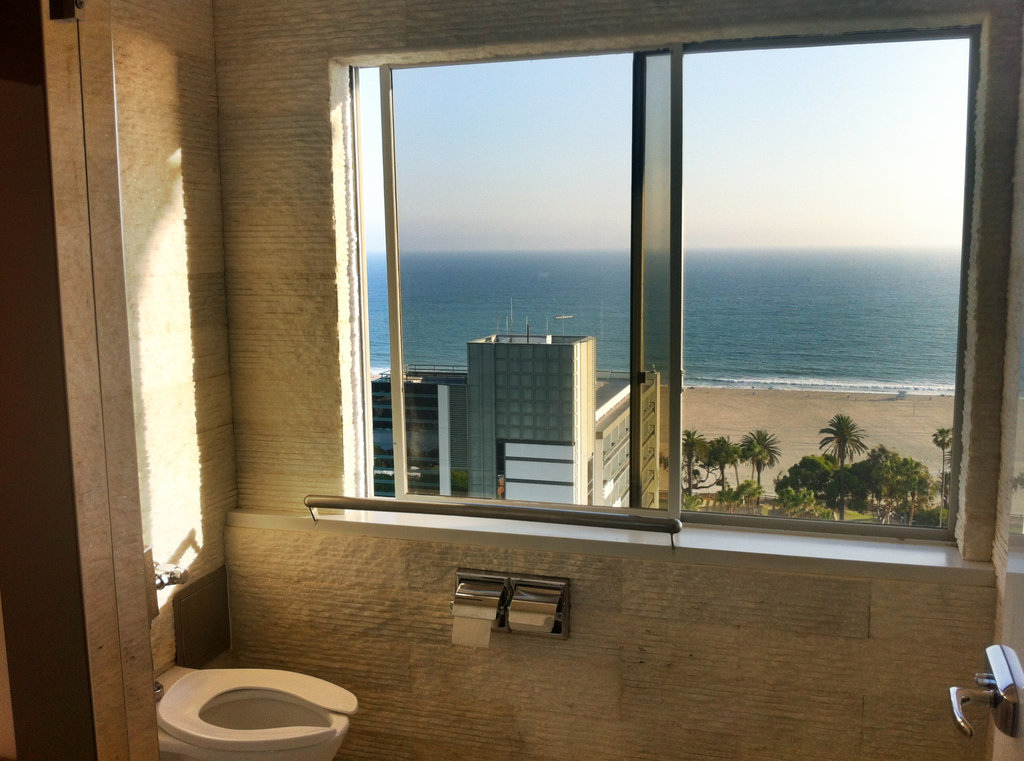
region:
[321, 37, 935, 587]
the window of a bathroom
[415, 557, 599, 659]
the toilet paper cover of a bathroom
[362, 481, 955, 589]
the window ledge of a bathroom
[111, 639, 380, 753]
the toilet of a bathroom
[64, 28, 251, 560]
the wall of a bathroom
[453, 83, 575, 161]
sky that is blue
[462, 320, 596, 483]
a building that is grey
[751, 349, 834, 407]
the foam is white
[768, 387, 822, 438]
the sand is brown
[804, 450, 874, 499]
the tree is green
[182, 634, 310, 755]
the seat of the toilet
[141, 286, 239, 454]
a ray of sunshine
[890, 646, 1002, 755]
a metal handle on the door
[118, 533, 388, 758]
A white porcilin toilet.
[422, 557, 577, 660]
A toilet paper holder.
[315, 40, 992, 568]
An open window.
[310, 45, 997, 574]
Beach view with palm trees.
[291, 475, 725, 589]
Chrome hand rail.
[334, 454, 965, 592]
A long brown window sill.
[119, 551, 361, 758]
A white horseshoe shaped toilet seat.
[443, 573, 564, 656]
Toilet paper rolls on the wall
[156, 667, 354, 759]
A toilet by the window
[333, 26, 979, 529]
A large open window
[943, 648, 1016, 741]
A silver handle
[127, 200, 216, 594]
Sunlight on the wall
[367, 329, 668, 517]
A building by the water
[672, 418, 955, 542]
Palm trees on the sand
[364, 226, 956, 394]
Water stretching into the distance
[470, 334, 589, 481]
it is a large grey building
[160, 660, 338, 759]
it is a white toilet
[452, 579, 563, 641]
toilet paper holder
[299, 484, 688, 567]
it is a silver rail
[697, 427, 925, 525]
the trees are green and tall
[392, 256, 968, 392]
the ocean is blue and nice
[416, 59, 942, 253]
the sky is blue and cloudless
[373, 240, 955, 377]
the ocean is huge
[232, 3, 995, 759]
wall made of stone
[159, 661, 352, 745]
white toilet seat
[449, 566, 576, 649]
two toilet paper dispensers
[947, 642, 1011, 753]
metal door handle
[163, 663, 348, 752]
white porcelain toilet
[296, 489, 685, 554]
hand rail attached to a windowsill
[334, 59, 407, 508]
the window is opened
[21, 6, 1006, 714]
a clean bath room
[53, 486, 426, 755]
a toilet in the background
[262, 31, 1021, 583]
window on the wall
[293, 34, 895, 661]
glass on the window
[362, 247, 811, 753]
buildings in the background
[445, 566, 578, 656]
toilet paper dispenser on the wall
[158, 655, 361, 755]
toilet against the wall